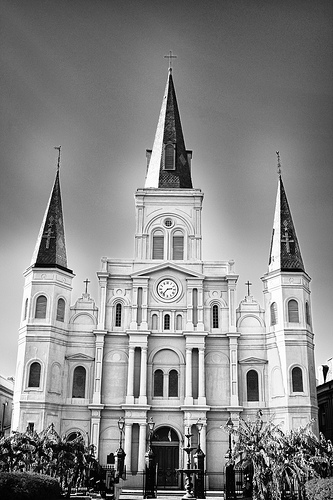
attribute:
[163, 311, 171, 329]
arch — black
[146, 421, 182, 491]
door — large, brown